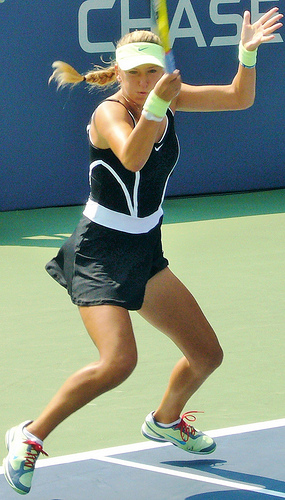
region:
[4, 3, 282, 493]
Young lady playing tennis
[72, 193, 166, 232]
White band around bottom of black top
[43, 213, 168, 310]
Black skirt of tennis player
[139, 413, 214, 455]
White, black and red tennis shoe on left foot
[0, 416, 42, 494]
Blue, white and red tennis shoe on right foot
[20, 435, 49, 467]
Red shoelace on right tennis shoe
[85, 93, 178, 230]
Tennis player wearing black and white top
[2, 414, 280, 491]
White strips on tennis court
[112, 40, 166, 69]
Lime screw cap on tennis player's head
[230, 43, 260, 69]
Lime band around left wrist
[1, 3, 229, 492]
A woman playing tennis.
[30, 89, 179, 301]
The woman is wearing a black and white tennis dress.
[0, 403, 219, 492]
The woman is wearing green and grey colored tennis shoes.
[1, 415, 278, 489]
White lines are painted on the tennis court.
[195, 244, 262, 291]
This part of the ground is green.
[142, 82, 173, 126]
The woman is wearing a green wrist band.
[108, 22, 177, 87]
The woman is wearing a green visor.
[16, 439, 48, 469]
Red laces on the tennis shoe.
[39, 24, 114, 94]
The woman's hair is braided.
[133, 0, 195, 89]
The woman is holding a racket.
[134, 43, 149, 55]
The Nike sign on the player's visor.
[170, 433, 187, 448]
The blue Nike sign on the player's right sneaker.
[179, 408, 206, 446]
The pink shoe laces on the player's right sneaker.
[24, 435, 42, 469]
The pink laces on the player's left sneaker.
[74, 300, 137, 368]
The player's left thigh.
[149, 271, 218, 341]
The player's right thigh.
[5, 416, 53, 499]
The player's left sneaker.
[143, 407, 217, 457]
The player's right sneaker.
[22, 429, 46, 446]
The white sock on the player's left foot.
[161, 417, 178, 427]
The white sock on the player's right foot.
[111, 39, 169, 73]
White visor with the nike emblem on it.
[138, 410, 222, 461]
Yellow tennis shoe with red laces.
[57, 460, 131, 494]
Blue colored tennis court.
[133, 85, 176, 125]
Yellow colored sweatband on woman's wrist.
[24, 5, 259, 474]
Woman playing a game of tennis.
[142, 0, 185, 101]
Tennis racket in woman's hand.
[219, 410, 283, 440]
White line indicating a boundary.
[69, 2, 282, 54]
Name of a sponsor on the wall.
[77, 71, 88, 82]
Black hair tie holding woman's braid in.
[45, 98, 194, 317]
Black and white tennis outfit.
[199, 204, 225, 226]
edge of a shade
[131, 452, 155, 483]
part of a white line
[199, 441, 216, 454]
edge of a shoe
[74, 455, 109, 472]
edge of a white line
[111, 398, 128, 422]
part of a green court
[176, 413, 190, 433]
part of a lace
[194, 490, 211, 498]
edge of a shade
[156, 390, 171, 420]
edge of a leg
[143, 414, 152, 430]
edge of a shoe